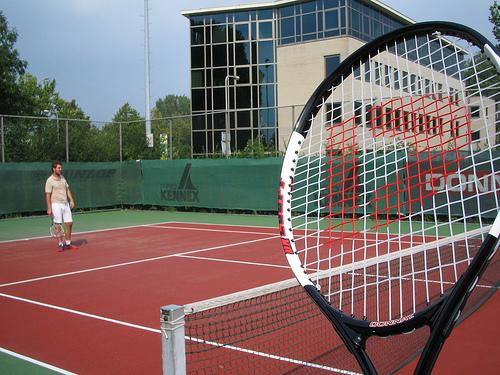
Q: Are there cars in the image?
A: No, there are no cars.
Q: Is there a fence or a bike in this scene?
A: Yes, there is a fence.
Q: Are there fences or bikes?
A: Yes, there is a fence.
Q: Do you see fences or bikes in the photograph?
A: Yes, there is a fence.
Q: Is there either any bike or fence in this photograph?
A: Yes, there is a fence.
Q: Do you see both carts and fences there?
A: No, there is a fence but no carts.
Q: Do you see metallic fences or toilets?
A: Yes, there is a metal fence.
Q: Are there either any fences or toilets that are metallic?
A: Yes, the fence is metallic.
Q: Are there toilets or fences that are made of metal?
A: Yes, the fence is made of metal.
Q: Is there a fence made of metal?
A: Yes, there is a fence that is made of metal.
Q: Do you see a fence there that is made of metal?
A: Yes, there is a fence that is made of metal.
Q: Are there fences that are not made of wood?
A: Yes, there is a fence that is made of metal.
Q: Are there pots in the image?
A: No, there are no pots.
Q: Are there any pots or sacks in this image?
A: No, there are no pots or sacks.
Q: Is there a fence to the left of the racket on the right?
A: Yes, there is a fence to the left of the racket.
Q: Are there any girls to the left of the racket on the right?
A: No, there is a fence to the left of the racket.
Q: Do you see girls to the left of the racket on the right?
A: No, there is a fence to the left of the racket.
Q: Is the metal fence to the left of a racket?
A: Yes, the fence is to the left of a racket.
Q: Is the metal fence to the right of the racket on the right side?
A: No, the fence is to the left of the tennis racket.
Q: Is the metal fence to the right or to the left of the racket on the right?
A: The fence is to the left of the racket.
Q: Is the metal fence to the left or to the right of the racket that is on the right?
A: The fence is to the left of the racket.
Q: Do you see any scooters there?
A: No, there are no scooters.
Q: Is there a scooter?
A: No, there are no scooters.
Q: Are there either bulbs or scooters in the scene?
A: No, there are no scooters or bulbs.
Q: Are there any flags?
A: No, there are no flags.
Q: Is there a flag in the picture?
A: No, there are no flags.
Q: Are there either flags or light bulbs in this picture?
A: No, there are no flags or light bulbs.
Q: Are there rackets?
A: Yes, there is a racket.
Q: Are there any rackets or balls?
A: Yes, there is a racket.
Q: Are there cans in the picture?
A: No, there are no cans.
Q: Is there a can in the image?
A: No, there are no cans.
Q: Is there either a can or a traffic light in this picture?
A: No, there are no cans or traffic lights.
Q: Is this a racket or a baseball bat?
A: This is a racket.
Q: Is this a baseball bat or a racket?
A: This is a racket.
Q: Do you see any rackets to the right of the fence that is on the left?
A: Yes, there is a racket to the right of the fence.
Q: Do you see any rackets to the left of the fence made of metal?
A: No, the racket is to the right of the fence.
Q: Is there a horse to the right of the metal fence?
A: No, there is a racket to the right of the fence.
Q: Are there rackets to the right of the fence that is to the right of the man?
A: Yes, there is a racket to the right of the fence.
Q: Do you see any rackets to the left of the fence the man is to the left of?
A: No, the racket is to the right of the fence.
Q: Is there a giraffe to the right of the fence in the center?
A: No, there is a racket to the right of the fence.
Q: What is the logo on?
A: The logo is on the fence.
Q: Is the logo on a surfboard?
A: No, the logo is on the fence.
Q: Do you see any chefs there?
A: No, there are no chefs.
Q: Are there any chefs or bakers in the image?
A: No, there are no chefs or bakers.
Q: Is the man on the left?
A: Yes, the man is on the left of the image.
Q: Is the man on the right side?
A: No, the man is on the left of the image.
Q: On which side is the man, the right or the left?
A: The man is on the left of the image.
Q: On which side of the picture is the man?
A: The man is on the left of the image.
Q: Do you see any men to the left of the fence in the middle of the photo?
A: Yes, there is a man to the left of the fence.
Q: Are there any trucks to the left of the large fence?
A: No, there is a man to the left of the fence.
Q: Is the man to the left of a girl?
A: No, the man is to the left of the fence.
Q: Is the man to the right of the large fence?
A: No, the man is to the left of the fence.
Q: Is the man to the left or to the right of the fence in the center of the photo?
A: The man is to the left of the fence.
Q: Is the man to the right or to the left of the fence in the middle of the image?
A: The man is to the left of the fence.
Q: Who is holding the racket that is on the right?
A: The man is holding the tennis racket.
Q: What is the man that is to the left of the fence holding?
A: The man is holding the tennis racket.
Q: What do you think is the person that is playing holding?
A: The man is holding the tennis racket.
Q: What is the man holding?
A: The man is holding the tennis racket.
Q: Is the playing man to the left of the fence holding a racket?
A: Yes, the man is holding a racket.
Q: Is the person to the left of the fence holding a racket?
A: Yes, the man is holding a racket.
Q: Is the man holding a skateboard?
A: No, the man is holding a racket.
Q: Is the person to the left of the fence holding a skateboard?
A: No, the man is holding a racket.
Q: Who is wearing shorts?
A: The man is wearing shorts.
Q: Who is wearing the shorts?
A: The man is wearing shorts.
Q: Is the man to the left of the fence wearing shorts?
A: Yes, the man is wearing shorts.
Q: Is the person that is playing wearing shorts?
A: Yes, the man is wearing shorts.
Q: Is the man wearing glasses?
A: No, the man is wearing shorts.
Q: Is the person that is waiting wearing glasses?
A: No, the man is wearing shorts.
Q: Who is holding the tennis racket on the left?
A: The man is holding the racket.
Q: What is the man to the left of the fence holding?
A: The man is holding the tennis racket.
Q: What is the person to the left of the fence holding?
A: The man is holding the tennis racket.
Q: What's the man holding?
A: The man is holding the tennis racket.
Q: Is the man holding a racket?
A: Yes, the man is holding a racket.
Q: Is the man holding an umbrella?
A: No, the man is holding a racket.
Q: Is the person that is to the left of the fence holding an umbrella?
A: No, the man is holding a racket.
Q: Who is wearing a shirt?
A: The man is wearing a shirt.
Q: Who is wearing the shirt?
A: The man is wearing a shirt.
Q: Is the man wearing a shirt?
A: Yes, the man is wearing a shirt.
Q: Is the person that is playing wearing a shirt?
A: Yes, the man is wearing a shirt.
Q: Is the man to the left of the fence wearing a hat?
A: No, the man is wearing a shirt.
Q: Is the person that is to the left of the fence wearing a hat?
A: No, the man is wearing a shirt.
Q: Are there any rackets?
A: Yes, there is a racket.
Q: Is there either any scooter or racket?
A: Yes, there is a racket.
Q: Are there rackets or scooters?
A: Yes, there is a racket.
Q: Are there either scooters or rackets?
A: Yes, there is a racket.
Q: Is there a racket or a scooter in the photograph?
A: Yes, there is a racket.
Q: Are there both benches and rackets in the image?
A: No, there is a racket but no benches.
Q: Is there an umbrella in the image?
A: No, there are no umbrellas.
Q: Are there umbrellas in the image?
A: No, there are no umbrellas.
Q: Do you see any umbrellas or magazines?
A: No, there are no umbrellas or magazines.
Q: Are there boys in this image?
A: No, there are no boys.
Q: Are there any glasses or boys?
A: No, there are no boys or glasses.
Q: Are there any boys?
A: No, there are no boys.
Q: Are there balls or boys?
A: No, there are no boys or balls.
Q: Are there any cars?
A: No, there are no cars.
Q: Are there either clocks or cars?
A: No, there are no cars or clocks.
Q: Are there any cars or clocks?
A: No, there are no cars or clocks.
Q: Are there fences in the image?
A: Yes, there is a fence.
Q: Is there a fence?
A: Yes, there is a fence.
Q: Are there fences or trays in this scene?
A: Yes, there is a fence.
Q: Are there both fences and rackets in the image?
A: Yes, there are both a fence and a racket.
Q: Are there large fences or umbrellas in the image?
A: Yes, there is a large fence.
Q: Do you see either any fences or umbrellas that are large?
A: Yes, the fence is large.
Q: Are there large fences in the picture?
A: Yes, there is a large fence.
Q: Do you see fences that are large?
A: Yes, there is a fence that is large.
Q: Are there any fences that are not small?
A: Yes, there is a large fence.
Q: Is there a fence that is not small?
A: Yes, there is a large fence.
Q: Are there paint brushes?
A: No, there are no paint brushes.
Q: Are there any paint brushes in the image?
A: No, there are no paint brushes.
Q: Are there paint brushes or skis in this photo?
A: No, there are no paint brushes or skis.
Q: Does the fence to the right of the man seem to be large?
A: Yes, the fence is large.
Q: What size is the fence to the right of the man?
A: The fence is large.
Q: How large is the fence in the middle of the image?
A: The fence is large.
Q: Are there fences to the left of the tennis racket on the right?
A: Yes, there is a fence to the left of the racket.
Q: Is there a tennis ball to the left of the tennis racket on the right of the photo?
A: No, there is a fence to the left of the racket.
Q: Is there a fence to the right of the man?
A: Yes, there is a fence to the right of the man.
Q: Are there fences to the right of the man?
A: Yes, there is a fence to the right of the man.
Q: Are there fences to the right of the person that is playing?
A: Yes, there is a fence to the right of the man.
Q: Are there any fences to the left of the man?
A: No, the fence is to the right of the man.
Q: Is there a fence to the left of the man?
A: No, the fence is to the right of the man.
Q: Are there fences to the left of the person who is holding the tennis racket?
A: No, the fence is to the right of the man.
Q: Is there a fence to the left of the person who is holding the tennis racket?
A: No, the fence is to the right of the man.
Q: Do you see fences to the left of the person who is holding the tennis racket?
A: No, the fence is to the right of the man.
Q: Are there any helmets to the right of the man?
A: No, there is a fence to the right of the man.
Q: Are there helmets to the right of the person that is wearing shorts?
A: No, there is a fence to the right of the man.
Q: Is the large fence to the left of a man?
A: No, the fence is to the right of a man.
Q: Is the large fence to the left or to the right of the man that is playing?
A: The fence is to the right of the man.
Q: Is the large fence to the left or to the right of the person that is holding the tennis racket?
A: The fence is to the right of the man.